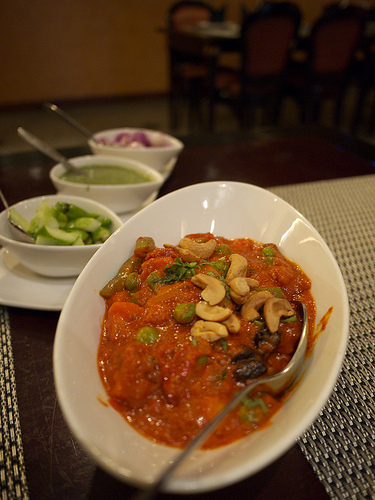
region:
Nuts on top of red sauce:
[167, 246, 300, 365]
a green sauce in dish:
[47, 139, 163, 209]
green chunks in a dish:
[28, 187, 100, 270]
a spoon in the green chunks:
[2, 187, 41, 243]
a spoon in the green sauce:
[20, 123, 121, 203]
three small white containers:
[6, 98, 189, 286]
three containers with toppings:
[5, 112, 188, 267]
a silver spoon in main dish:
[108, 295, 351, 493]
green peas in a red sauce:
[128, 295, 231, 379]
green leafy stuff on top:
[139, 245, 218, 299]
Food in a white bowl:
[117, 226, 300, 432]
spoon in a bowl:
[219, 295, 320, 401]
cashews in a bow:
[194, 250, 288, 343]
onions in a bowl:
[91, 119, 166, 151]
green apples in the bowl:
[23, 203, 84, 246]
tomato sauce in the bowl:
[120, 329, 201, 404]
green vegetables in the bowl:
[103, 251, 164, 316]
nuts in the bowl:
[201, 234, 287, 348]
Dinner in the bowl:
[111, 253, 274, 412]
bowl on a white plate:
[7, 174, 83, 319]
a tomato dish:
[151, 228, 277, 433]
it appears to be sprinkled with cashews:
[180, 245, 267, 347]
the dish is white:
[158, 197, 372, 348]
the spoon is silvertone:
[191, 266, 312, 455]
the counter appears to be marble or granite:
[23, 342, 49, 417]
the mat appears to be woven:
[329, 190, 365, 249]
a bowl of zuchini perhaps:
[23, 195, 96, 258]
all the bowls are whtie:
[1, 106, 209, 327]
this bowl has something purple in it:
[105, 125, 178, 159]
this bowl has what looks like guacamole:
[55, 153, 174, 196]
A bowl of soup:
[44, 173, 352, 495]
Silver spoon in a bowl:
[144, 299, 310, 497]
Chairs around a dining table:
[151, 13, 371, 135]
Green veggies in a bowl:
[3, 192, 123, 280]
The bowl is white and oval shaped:
[46, 178, 352, 497]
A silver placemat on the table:
[261, 171, 373, 497]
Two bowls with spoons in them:
[11, 93, 182, 218]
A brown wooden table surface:
[1, 123, 372, 499]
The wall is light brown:
[0, 1, 369, 102]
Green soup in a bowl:
[48, 152, 164, 215]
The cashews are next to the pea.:
[169, 286, 233, 346]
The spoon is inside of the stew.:
[241, 298, 316, 409]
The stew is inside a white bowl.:
[99, 198, 335, 405]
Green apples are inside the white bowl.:
[2, 185, 120, 263]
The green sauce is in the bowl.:
[49, 156, 147, 194]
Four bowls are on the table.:
[0, 78, 359, 489]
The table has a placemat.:
[244, 396, 368, 497]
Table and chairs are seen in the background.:
[153, 1, 370, 116]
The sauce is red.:
[149, 347, 200, 389]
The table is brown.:
[26, 432, 89, 493]